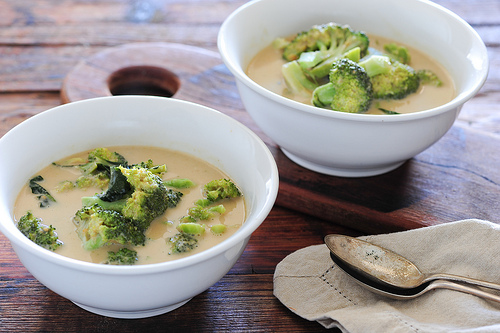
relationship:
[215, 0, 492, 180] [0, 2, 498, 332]
bowl on table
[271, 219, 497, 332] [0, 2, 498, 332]
napkin on table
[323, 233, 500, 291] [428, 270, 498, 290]
spoon has handle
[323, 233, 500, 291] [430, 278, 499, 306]
spoon has handle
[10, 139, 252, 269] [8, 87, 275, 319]
sauce in bowl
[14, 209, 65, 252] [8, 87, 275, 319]
broccoli in bowl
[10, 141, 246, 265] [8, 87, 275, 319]
sauce inside bowl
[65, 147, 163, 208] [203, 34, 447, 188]
broccoli in a bowl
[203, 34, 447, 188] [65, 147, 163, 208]
bowl has broccoli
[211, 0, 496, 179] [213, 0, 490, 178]
curves on a bowl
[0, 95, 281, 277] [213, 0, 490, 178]
curves on a bowl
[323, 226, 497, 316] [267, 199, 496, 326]
spoon on a napkin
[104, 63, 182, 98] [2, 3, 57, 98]
hole in a table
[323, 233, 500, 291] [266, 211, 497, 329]
spoon on a napkin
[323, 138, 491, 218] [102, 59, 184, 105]
wood around hole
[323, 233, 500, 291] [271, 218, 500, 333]
spoon on napkin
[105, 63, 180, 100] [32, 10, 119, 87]
hole in table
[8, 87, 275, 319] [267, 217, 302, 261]
bowl on table